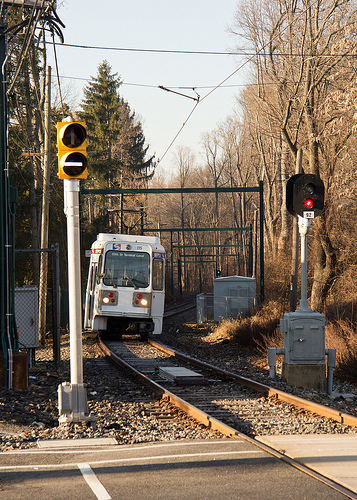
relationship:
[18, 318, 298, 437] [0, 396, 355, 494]
gravel on road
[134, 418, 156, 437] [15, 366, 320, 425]
pepples in ground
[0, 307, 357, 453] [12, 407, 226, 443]
gravel in ground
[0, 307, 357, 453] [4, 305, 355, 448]
gravel in ground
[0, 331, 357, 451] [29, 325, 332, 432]
pepples in ground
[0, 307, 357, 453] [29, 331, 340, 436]
gravel in ground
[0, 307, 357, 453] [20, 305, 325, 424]
gravel in ground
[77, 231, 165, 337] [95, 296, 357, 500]
train on railroad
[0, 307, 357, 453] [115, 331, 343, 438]
gravel between tracks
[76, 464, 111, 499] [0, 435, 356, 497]
lines painted on road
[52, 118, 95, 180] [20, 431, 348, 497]
signal on side of road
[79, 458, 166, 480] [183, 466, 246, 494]
shadow of poles on road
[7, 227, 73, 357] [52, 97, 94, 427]
fence behind traffic light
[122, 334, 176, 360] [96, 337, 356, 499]
sun on tracks